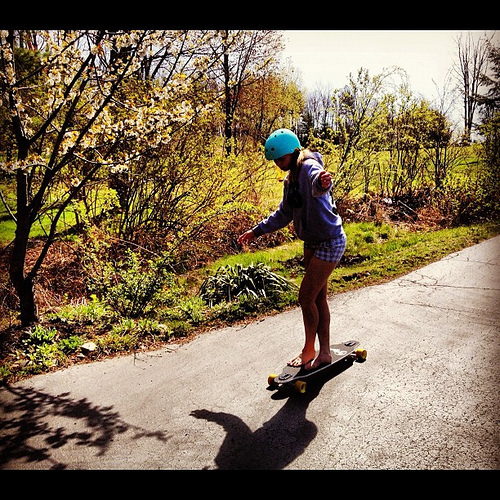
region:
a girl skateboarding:
[219, 77, 403, 442]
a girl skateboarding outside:
[192, 38, 497, 385]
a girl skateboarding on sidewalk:
[198, 91, 481, 492]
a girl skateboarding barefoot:
[208, 110, 433, 437]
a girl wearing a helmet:
[177, 88, 377, 325]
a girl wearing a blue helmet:
[216, 100, 490, 438]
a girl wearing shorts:
[194, 92, 496, 452]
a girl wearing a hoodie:
[191, 81, 437, 414]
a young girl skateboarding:
[219, 103, 408, 405]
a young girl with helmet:
[154, 73, 461, 405]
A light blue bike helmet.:
[260, 122, 306, 155]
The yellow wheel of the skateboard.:
[266, 373, 279, 388]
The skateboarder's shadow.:
[181, 391, 327, 470]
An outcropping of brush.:
[28, 256, 192, 374]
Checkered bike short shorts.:
[315, 234, 351, 265]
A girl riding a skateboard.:
[231, 123, 350, 365]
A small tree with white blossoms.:
[0, 33, 237, 165]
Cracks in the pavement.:
[401, 271, 498, 320]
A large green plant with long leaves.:
[200, 263, 290, 307]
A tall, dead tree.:
[455, 38, 495, 148]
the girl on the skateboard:
[238, 122, 345, 366]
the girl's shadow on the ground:
[182, 382, 317, 469]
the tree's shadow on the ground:
[4, 380, 173, 463]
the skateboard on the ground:
[265, 337, 367, 392]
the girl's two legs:
[288, 249, 336, 370]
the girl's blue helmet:
[264, 126, 301, 158]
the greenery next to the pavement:
[25, 77, 442, 294]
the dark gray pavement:
[385, 285, 498, 440]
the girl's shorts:
[292, 237, 347, 264]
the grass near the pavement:
[365, 231, 436, 259]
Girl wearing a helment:
[249, 123, 301, 165]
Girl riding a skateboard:
[243, 112, 348, 404]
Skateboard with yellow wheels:
[288, 378, 310, 392]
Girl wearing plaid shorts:
[298, 231, 355, 264]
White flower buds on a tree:
[69, 65, 178, 161]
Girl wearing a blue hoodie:
[260, 164, 350, 246]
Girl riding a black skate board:
[271, 199, 361, 412]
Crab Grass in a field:
[198, 265, 288, 305]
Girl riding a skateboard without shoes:
[291, 342, 332, 375]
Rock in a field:
[69, 330, 106, 360]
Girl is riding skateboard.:
[218, 133, 384, 409]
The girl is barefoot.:
[221, 107, 396, 424]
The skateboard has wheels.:
[253, 332, 385, 413]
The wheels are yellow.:
[249, 326, 387, 411]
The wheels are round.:
[249, 320, 409, 431]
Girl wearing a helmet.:
[223, 125, 382, 411]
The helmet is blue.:
[243, 118, 315, 183]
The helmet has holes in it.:
[241, 124, 320, 183]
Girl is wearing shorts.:
[229, 125, 386, 412]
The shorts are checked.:
[289, 224, 356, 278]